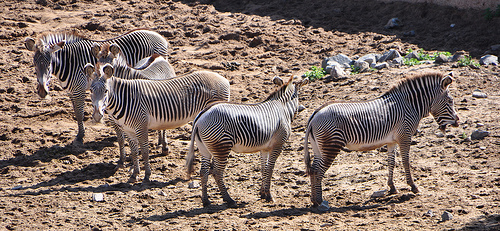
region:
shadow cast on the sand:
[92, 161, 223, 205]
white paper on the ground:
[73, 183, 145, 196]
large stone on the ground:
[469, 122, 489, 143]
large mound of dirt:
[194, 9, 228, 36]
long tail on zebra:
[290, 120, 323, 193]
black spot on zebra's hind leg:
[320, 133, 342, 168]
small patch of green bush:
[300, 57, 332, 79]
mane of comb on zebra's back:
[374, 60, 454, 80]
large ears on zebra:
[81, 57, 145, 95]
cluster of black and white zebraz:
[28, 18, 462, 170]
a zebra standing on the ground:
[302, 61, 463, 218]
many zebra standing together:
[55, 64, 474, 218]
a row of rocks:
[311, 43, 403, 78]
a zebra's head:
[80, 61, 119, 127]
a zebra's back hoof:
[307, 198, 337, 218]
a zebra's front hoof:
[406, 181, 426, 198]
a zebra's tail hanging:
[180, 120, 201, 182]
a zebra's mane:
[24, 26, 85, 53]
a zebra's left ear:
[98, 59, 115, 82]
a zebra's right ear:
[82, 62, 94, 85]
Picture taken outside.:
[39, 16, 474, 193]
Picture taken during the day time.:
[8, 6, 492, 206]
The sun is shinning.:
[14, 12, 495, 199]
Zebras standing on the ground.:
[39, 27, 465, 230]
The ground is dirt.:
[36, 124, 90, 190]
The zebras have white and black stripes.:
[19, 12, 499, 197]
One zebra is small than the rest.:
[210, 72, 289, 205]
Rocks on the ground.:
[282, 45, 475, 69]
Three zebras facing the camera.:
[28, 37, 180, 176]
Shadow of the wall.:
[353, 6, 494, 51]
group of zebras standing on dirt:
[24, 16, 496, 211]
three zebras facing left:
[21, 13, 242, 168]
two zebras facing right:
[200, 89, 478, 194]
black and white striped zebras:
[28, 25, 473, 202]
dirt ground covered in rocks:
[21, 17, 488, 221]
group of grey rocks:
[321, 40, 412, 76]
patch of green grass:
[407, 40, 478, 73]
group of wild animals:
[20, 19, 495, 194]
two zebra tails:
[176, 114, 356, 184]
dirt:
[181, 13, 305, 71]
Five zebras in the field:
[24, 16, 480, 206]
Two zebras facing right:
[176, 59, 471, 210]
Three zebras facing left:
[13, 16, 244, 198]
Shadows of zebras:
[3, 131, 129, 204]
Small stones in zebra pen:
[316, 39, 496, 77]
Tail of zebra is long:
[293, 108, 317, 180]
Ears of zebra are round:
[76, 57, 119, 82]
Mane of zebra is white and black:
[106, 59, 167, 82]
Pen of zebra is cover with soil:
[3, 3, 499, 228]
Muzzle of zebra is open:
[435, 108, 467, 138]